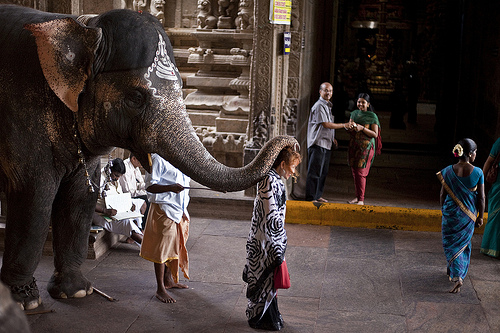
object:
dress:
[101, 169, 146, 238]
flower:
[265, 214, 283, 234]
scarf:
[350, 110, 383, 157]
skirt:
[139, 204, 190, 284]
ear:
[23, 13, 103, 112]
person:
[242, 146, 303, 331]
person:
[138, 153, 190, 305]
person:
[347, 93, 383, 205]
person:
[304, 82, 353, 203]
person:
[436, 138, 485, 293]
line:
[285, 200, 442, 232]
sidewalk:
[311, 210, 437, 256]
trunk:
[159, 110, 302, 193]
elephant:
[0, 0, 302, 331]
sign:
[269, 0, 293, 25]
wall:
[264, 1, 311, 141]